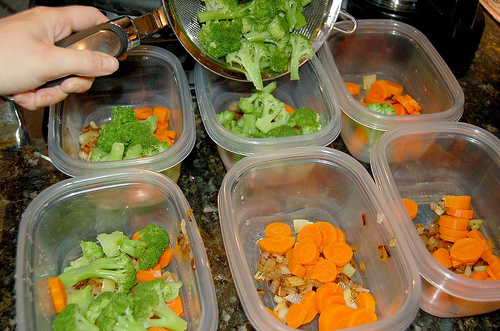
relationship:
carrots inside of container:
[261, 215, 377, 323] [219, 146, 425, 329]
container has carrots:
[219, 146, 425, 329] [261, 215, 377, 323]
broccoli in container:
[60, 218, 175, 330] [10, 168, 222, 327]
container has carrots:
[321, 13, 469, 155] [344, 65, 438, 113]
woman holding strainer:
[2, 2, 120, 110] [56, 0, 359, 88]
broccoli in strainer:
[190, 2, 311, 84] [56, 0, 359, 88]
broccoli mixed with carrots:
[60, 218, 175, 330] [46, 232, 186, 323]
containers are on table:
[34, 9, 495, 331] [3, 6, 499, 328]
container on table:
[219, 146, 425, 329] [3, 6, 499, 328]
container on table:
[45, 44, 194, 177] [3, 6, 499, 328]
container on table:
[196, 39, 347, 151] [3, 6, 499, 328]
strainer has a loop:
[56, 0, 359, 88] [332, 7, 356, 40]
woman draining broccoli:
[2, 2, 120, 110] [60, 218, 175, 330]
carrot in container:
[296, 239, 316, 266] [219, 146, 425, 329]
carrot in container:
[155, 107, 171, 128] [45, 44, 194, 177]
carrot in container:
[454, 237, 482, 267] [372, 116, 499, 329]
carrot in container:
[346, 76, 362, 98] [321, 13, 469, 155]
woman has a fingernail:
[2, 2, 120, 110] [103, 52, 121, 73]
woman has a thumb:
[2, 2, 120, 110] [52, 45, 122, 81]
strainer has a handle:
[56, 0, 359, 88] [51, 8, 169, 72]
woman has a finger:
[2, 2, 120, 110] [48, 5, 107, 34]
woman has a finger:
[2, 2, 120, 110] [12, 95, 34, 111]